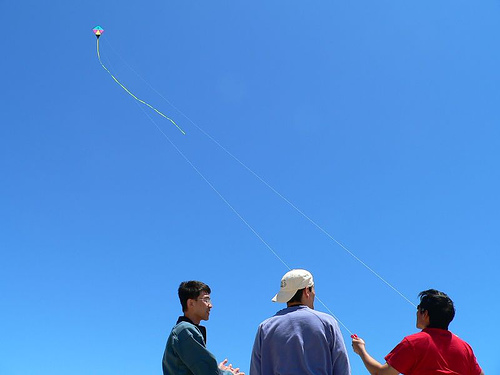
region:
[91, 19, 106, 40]
The kite is diamond.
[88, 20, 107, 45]
A multi colored kite.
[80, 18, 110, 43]
A kite in the air.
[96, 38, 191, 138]
Yellow kite strings.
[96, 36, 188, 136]
The yellow string of a kite.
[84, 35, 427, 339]
The man kite strings are white.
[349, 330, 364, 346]
A man holds the handle.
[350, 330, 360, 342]
The handle is red.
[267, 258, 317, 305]
The mans hat is backwards.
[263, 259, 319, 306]
The mans hat is white.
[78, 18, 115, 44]
A kite in the sky.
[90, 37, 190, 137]
The tail of the kite.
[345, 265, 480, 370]
The man is flying a kite.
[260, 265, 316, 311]
The man is wearing a hat.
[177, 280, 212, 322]
The man is wearing glasses.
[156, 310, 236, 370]
The man is wearing a blue jacket.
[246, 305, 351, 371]
The shirt is blue.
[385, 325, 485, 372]
A bright red shirt.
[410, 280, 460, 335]
The man has short hair.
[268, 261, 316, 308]
The hat is white.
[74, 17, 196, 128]
Kite in the sky.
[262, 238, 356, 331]
Hat on the man.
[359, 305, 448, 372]
Man with a red shirt.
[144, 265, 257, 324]
Man with black hair.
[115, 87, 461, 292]
Blue sky with a kite.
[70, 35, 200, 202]
Tail of the kite.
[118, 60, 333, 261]
String of the kite.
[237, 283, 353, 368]
purple shirt on the man.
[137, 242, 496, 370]
Three men flying a kite.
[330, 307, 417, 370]
Man holding a kite.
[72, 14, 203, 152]
kite flying in the sky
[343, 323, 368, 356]
kite string that connects to kite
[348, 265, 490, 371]
man wearing red shirt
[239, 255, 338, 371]
man wearing blue shirt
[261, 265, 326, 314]
man wearing white hat backwards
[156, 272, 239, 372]
man wearing green jacket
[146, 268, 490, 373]
three men flying kites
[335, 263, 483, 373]
man looking up at kite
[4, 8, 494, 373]
three guys flying a kite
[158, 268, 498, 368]
three men talking to each other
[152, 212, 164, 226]
part of the sky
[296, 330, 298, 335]
back of a man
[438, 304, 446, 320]
head of a man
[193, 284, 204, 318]
face of a man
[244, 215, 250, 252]
rope of a kite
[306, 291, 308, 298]
face of a man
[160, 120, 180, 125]
tip of a kite